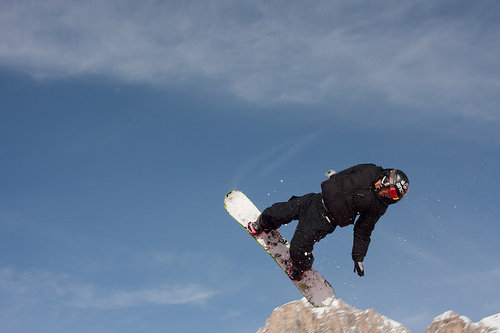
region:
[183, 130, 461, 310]
Man in the sky.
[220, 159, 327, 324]
Skateboard under the man.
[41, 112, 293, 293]
Blue sky in the background.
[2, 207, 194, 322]
White clouds in the sky.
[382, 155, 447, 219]
Helmet on the man.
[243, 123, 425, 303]
Black outfit on the boarder.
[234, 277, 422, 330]
Mountains in the background.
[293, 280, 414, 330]
Snow on the mountains.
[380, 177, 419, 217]
Red goggles on the man.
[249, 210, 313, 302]
Man's shoes on the board.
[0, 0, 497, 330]
sky has light clouds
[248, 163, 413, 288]
snowboarder performing a trick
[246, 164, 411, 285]
snowboarder wearing goggles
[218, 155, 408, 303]
snowboarder riding snowboard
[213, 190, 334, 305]
a long white snowboard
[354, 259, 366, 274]
black and white snow gloves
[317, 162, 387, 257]
black down feather winter jacket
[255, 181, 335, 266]
black winter snow pants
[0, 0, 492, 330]
sky is light blue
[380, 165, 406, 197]
black and white snow helmet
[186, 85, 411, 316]
athlete attached to snowboard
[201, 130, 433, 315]
snowboarder jumping in air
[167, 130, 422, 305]
snowboarder leaning to one side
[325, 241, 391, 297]
gloved hand reaching away from body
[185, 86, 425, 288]
black jacket with black pants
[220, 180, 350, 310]
white board with dark splotches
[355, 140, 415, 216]
black helmet with white writing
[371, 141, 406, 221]
red and yellow goggles over eyes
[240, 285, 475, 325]
tops of rocky peaks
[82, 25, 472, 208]
thin clouds over skateboarder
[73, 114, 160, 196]
the sky is blue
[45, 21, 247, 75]
the cloud is white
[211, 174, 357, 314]
the snow board is white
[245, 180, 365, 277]
person is wearing pants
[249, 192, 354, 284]
the pants are black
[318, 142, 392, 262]
the person is wearing a jacket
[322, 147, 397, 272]
the jacket is black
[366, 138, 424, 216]
the man is wearing a helmet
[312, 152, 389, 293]
the man is wearing gloves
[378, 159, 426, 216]
the helmet is black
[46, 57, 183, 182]
part of the sky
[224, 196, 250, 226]
part of a snow board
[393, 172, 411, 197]
part of a helmet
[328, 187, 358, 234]
part of a black jacket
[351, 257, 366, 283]
left hand of the skater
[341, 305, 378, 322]
part of a hill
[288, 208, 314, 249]
part of a black track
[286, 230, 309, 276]
left leg of the skater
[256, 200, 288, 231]
right leg of the skater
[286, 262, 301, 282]
a shoe on the left shoe